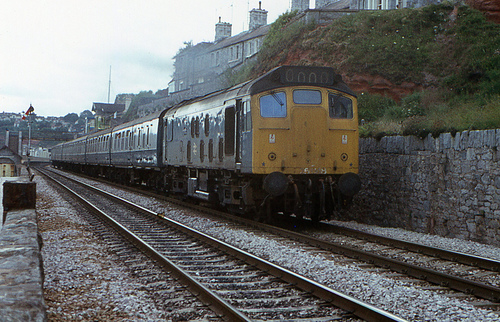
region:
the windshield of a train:
[256, 87, 286, 120]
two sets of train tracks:
[29, 158, 498, 318]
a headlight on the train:
[264, 146, 282, 161]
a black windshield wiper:
[267, 86, 286, 107]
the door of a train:
[216, 99, 240, 164]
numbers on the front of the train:
[278, 66, 336, 88]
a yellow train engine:
[159, 60, 365, 232]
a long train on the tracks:
[48, 54, 370, 231]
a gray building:
[172, 4, 287, 96]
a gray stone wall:
[357, 133, 498, 244]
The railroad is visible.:
[121, 150, 205, 262]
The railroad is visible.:
[151, 228, 253, 313]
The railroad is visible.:
[77, 161, 209, 291]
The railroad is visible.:
[162, 267, 210, 312]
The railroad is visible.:
[125, 181, 277, 319]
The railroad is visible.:
[187, 267, 242, 317]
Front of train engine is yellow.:
[162, 56, 375, 228]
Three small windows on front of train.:
[254, 76, 364, 136]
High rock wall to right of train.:
[361, 117, 496, 247]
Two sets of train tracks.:
[111, 210, 484, 319]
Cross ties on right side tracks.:
[297, 217, 498, 297]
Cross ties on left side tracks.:
[71, 190, 353, 318]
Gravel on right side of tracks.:
[320, 191, 495, 262]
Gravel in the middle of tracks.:
[186, 223, 458, 320]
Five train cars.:
[43, 52, 363, 221]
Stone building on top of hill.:
[175, 0, 388, 89]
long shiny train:
[28, 59, 373, 230]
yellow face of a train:
[230, 63, 367, 203]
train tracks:
[24, 153, 499, 319]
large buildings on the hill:
[173, 0, 461, 102]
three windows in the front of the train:
[254, 81, 362, 128]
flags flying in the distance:
[15, 101, 38, 121]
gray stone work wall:
[353, 128, 498, 253]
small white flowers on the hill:
[339, 14, 434, 69]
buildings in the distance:
[2, 102, 95, 139]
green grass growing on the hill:
[272, 0, 498, 137]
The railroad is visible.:
[137, 238, 212, 306]